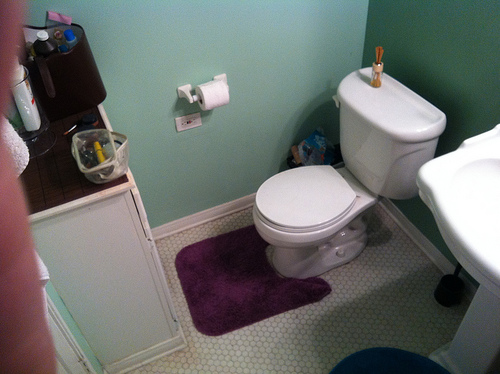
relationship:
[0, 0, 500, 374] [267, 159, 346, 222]
bathroom with lid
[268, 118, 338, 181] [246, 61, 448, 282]
rack next to toilet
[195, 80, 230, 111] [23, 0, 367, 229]
napkin roll hanging on wall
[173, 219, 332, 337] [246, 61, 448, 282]
mat in front toilet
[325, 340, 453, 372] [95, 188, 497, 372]
mat on floor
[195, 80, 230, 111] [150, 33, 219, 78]
napkin roll on wall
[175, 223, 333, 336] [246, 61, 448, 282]
mat around toilet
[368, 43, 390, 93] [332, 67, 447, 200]
fragrance dispenser on tank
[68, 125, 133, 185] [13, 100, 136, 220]
bag on counter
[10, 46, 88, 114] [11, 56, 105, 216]
bottles on counter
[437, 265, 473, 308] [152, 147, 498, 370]
toilet brush on floor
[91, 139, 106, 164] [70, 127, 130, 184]
mascara in bag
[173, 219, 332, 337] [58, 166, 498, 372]
mat on floor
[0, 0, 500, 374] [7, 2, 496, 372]
bathroom in bathroom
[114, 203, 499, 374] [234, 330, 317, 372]
floor on floor